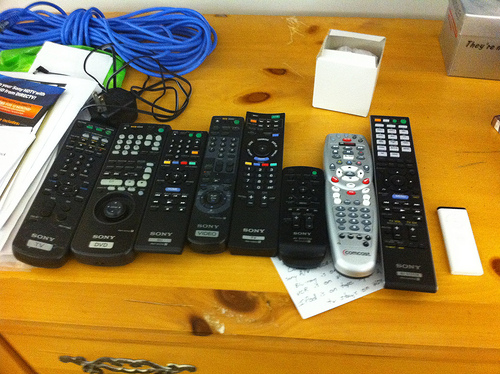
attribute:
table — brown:
[2, 8, 499, 372]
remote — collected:
[373, 110, 433, 297]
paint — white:
[205, 305, 248, 335]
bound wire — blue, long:
[0, 0, 220, 80]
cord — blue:
[2, 3, 224, 83]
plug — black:
[72, 35, 201, 130]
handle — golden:
[52, 350, 201, 372]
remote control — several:
[348, 120, 423, 240]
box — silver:
[441, 0, 498, 78]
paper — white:
[265, 234, 392, 328]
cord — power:
[81, 41, 191, 124]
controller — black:
[12, 118, 114, 268]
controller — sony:
[68, 122, 169, 264]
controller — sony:
[134, 127, 204, 254]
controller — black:
[185, 114, 245, 251]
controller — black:
[228, 109, 283, 255]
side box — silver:
[413, 6, 498, 68]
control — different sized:
[10, 86, 122, 269]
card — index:
[264, 226, 392, 321]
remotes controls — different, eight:
[2, 98, 447, 296]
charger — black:
[75, 41, 191, 126]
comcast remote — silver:
[317, 129, 376, 279]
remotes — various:
[12, 113, 442, 294]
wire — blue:
[66, 7, 154, 91]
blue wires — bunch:
[2, 0, 224, 82]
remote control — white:
[8, 116, 121, 272]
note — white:
[303, 275, 343, 308]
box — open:
[312, 26, 389, 116]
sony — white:
[84, 232, 114, 253]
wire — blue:
[1, 5, 215, 85]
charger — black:
[78, 39, 197, 132]